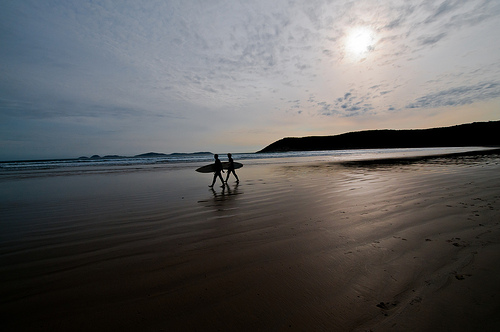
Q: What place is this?
A: It is a beach.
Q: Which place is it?
A: It is a beach.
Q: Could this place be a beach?
A: Yes, it is a beach.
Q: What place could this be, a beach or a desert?
A: It is a beach.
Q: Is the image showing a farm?
A: No, the picture is showing a beach.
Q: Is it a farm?
A: No, it is a beach.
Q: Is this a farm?
A: No, it is a beach.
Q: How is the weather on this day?
A: It is cloudy.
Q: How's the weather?
A: It is cloudy.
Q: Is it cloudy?
A: Yes, it is cloudy.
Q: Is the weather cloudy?
A: Yes, it is cloudy.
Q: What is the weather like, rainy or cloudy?
A: It is cloudy.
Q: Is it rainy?
A: No, it is cloudy.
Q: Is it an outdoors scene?
A: Yes, it is outdoors.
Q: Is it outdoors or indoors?
A: It is outdoors.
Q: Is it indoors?
A: No, it is outdoors.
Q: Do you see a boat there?
A: No, there are no boats.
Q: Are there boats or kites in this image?
A: No, there are no boats or kites.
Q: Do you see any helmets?
A: No, there are no helmets.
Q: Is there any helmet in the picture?
A: No, there are no helmets.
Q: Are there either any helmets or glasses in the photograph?
A: No, there are no helmets or glasses.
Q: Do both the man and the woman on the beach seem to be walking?
A: Yes, both the man and the woman are walking.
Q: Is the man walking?
A: Yes, the man is walking.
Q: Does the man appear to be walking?
A: Yes, the man is walking.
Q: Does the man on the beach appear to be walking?
A: Yes, the man is walking.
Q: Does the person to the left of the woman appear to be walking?
A: Yes, the man is walking.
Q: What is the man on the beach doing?
A: The man is walking.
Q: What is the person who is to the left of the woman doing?
A: The man is walking.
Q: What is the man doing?
A: The man is walking.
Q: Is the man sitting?
A: No, the man is walking.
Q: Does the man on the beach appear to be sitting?
A: No, the man is walking.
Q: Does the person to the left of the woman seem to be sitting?
A: No, the man is walking.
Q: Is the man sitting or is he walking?
A: The man is walking.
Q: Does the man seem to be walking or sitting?
A: The man is walking.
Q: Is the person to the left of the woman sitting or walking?
A: The man is walking.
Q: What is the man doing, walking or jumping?
A: The man is walking.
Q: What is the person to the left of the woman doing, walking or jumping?
A: The man is walking.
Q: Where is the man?
A: The man is on the beach.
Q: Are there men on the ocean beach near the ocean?
A: Yes, there is a man on the beach.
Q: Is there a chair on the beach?
A: No, there is a man on the beach.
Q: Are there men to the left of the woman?
A: Yes, there is a man to the left of the woman.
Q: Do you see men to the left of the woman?
A: Yes, there is a man to the left of the woman.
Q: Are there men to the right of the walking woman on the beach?
A: No, the man is to the left of the woman.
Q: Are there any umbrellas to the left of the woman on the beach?
A: No, there is a man to the left of the woman.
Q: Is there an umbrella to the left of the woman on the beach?
A: No, there is a man to the left of the woman.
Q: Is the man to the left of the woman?
A: Yes, the man is to the left of the woman.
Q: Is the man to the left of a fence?
A: No, the man is to the left of the woman.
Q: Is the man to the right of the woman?
A: No, the man is to the left of the woman.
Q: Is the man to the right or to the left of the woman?
A: The man is to the left of the woman.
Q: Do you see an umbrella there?
A: No, there are no umbrellas.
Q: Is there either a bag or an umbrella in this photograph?
A: No, there are no umbrellas or bags.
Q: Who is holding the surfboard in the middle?
A: The people are holding the surfboard.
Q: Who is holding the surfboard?
A: The people are holding the surfboard.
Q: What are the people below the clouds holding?
A: The people are holding the surfboard.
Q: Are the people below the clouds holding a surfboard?
A: Yes, the people are holding a surfboard.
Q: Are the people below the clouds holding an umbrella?
A: No, the people are holding a surfboard.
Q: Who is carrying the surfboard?
A: The people are carrying the surfboard.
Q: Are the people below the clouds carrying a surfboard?
A: Yes, the people are carrying a surfboard.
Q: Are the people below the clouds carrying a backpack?
A: No, the people are carrying a surfboard.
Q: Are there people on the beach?
A: Yes, there are people on the beach.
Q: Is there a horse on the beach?
A: No, there are people on the beach.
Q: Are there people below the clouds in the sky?
A: Yes, there are people below the clouds.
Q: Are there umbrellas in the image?
A: No, there are no umbrellas.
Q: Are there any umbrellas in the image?
A: No, there are no umbrellas.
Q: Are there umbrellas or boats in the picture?
A: No, there are no umbrellas or boats.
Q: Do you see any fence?
A: No, there are no fences.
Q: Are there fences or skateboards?
A: No, there are no fences or skateboards.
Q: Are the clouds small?
A: Yes, the clouds are small.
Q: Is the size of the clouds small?
A: Yes, the clouds are small.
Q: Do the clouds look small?
A: Yes, the clouds are small.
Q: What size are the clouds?
A: The clouds are small.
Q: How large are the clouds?
A: The clouds are small.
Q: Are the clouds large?
A: No, the clouds are small.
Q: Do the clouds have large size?
A: No, the clouds are small.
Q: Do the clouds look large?
A: No, the clouds are small.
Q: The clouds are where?
A: The clouds are in the sky.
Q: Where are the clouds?
A: The clouds are in the sky.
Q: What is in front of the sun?
A: The clouds are in front of the sun.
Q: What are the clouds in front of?
A: The clouds are in front of the sun.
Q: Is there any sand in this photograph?
A: Yes, there is sand.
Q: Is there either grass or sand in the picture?
A: Yes, there is sand.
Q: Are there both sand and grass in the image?
A: No, there is sand but no grass.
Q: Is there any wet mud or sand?
A: Yes, there is wet sand.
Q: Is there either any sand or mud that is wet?
A: Yes, the sand is wet.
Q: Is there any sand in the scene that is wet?
A: Yes, there is sand that is wet.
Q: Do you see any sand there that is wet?
A: Yes, there is sand that is wet.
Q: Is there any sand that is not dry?
A: Yes, there is wet sand.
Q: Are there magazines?
A: No, there are no magazines.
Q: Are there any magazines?
A: No, there are no magazines.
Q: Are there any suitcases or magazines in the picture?
A: No, there are no magazines or suitcases.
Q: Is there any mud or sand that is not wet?
A: No, there is sand but it is wet.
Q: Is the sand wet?
A: Yes, the sand is wet.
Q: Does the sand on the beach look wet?
A: Yes, the sand is wet.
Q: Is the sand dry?
A: No, the sand is wet.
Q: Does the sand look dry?
A: No, the sand is wet.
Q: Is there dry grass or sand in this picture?
A: No, there is sand but it is wet.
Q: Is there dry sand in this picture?
A: No, there is sand but it is wet.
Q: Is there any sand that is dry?
A: No, there is sand but it is wet.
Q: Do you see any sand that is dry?
A: No, there is sand but it is wet.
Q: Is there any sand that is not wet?
A: No, there is sand but it is wet.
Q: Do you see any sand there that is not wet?
A: No, there is sand but it is wet.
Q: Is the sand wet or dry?
A: The sand is wet.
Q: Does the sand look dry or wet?
A: The sand is wet.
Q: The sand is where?
A: The sand is on the beach.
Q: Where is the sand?
A: The sand is on the beach.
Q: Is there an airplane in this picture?
A: No, there are no airplanes.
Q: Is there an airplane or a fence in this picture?
A: No, there are no airplanes or fences.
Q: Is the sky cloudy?
A: Yes, the sky is cloudy.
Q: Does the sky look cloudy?
A: Yes, the sky is cloudy.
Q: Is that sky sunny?
A: No, the sky is cloudy.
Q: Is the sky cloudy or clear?
A: The sky is cloudy.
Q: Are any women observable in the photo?
A: Yes, there is a woman.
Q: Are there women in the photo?
A: Yes, there is a woman.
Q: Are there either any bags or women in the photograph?
A: Yes, there is a woman.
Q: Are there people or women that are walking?
A: Yes, the woman is walking.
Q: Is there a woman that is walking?
A: Yes, there is a woman that is walking.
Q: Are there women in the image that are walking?
A: Yes, there is a woman that is walking.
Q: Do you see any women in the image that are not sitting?
A: Yes, there is a woman that is walking .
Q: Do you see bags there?
A: No, there are no bags.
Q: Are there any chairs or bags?
A: No, there are no bags or chairs.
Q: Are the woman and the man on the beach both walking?
A: Yes, both the woman and the man are walking.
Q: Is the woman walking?
A: Yes, the woman is walking.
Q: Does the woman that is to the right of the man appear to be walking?
A: Yes, the woman is walking.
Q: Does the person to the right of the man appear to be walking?
A: Yes, the woman is walking.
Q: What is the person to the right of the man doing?
A: The woman is walking.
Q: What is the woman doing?
A: The woman is walking.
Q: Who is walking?
A: The woman is walking.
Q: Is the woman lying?
A: No, the woman is walking.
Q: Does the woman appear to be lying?
A: No, the woman is walking.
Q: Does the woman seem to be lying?
A: No, the woman is walking.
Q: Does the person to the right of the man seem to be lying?
A: No, the woman is walking.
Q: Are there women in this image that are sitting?
A: No, there is a woman but she is walking.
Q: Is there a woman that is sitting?
A: No, there is a woman but she is walking.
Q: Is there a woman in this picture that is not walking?
A: No, there is a woman but she is walking.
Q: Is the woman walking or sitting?
A: The woman is walking.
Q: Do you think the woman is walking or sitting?
A: The woman is walking.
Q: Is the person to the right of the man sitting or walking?
A: The woman is walking.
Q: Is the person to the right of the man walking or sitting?
A: The woman is walking.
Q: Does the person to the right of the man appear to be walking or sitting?
A: The woman is walking.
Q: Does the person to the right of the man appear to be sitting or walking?
A: The woman is walking.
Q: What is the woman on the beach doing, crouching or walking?
A: The woman is walking.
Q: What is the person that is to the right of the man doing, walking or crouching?
A: The woman is walking.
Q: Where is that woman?
A: The woman is on the beach.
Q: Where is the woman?
A: The woman is on the beach.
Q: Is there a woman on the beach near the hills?
A: Yes, there is a woman on the beach.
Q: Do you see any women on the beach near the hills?
A: Yes, there is a woman on the beach.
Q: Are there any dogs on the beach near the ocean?
A: No, there is a woman on the beach.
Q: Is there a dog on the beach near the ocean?
A: No, there is a woman on the beach.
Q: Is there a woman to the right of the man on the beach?
A: Yes, there is a woman to the right of the man.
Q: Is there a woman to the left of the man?
A: No, the woman is to the right of the man.